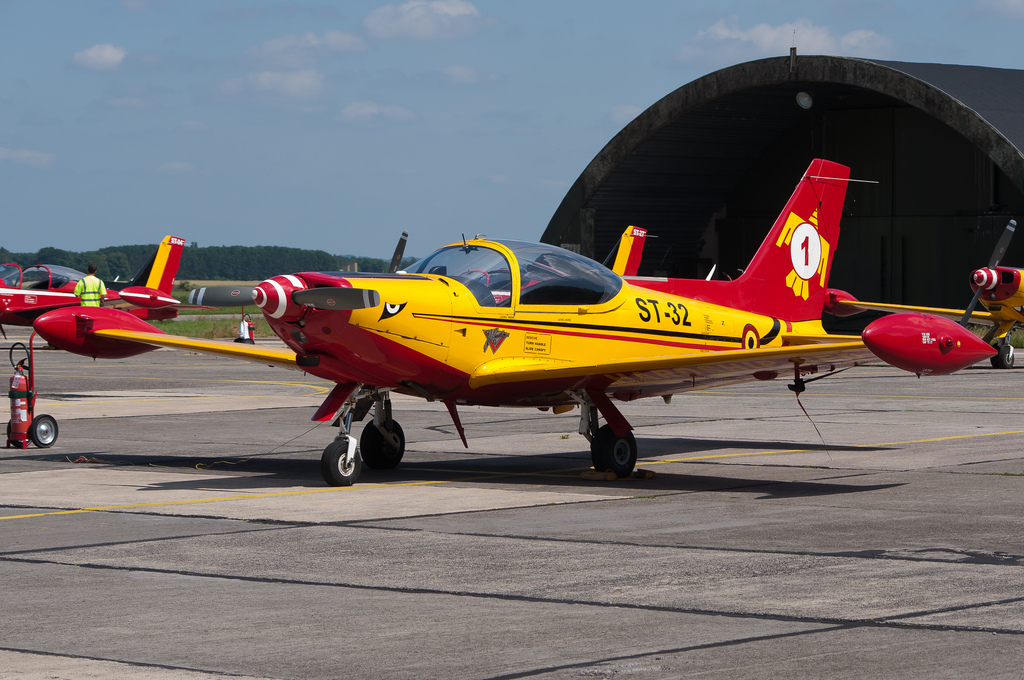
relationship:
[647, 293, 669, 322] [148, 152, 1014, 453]
letter on airplane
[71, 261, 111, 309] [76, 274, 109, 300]
man wearing jacket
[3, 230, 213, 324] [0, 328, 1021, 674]
airplane parked on airport tarmac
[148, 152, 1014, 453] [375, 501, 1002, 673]
airplane on road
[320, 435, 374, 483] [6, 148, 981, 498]
wheel on airplane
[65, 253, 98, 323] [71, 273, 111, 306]
man in jacket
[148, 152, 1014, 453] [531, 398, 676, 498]
airplane has a tire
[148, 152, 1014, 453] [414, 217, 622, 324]
airplane has a window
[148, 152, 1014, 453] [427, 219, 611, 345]
airplane has a window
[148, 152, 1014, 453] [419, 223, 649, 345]
airplane has a window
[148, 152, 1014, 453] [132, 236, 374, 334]
airplane has a propeller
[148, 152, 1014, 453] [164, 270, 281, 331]
airplane has propeller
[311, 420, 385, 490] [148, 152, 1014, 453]
wheel of airplane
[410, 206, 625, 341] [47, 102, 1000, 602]
glasses of plane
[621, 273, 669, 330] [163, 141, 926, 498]
letter on plane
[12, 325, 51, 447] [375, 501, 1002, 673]
fire extinguisher on road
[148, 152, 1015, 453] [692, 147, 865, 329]
airplane has tail